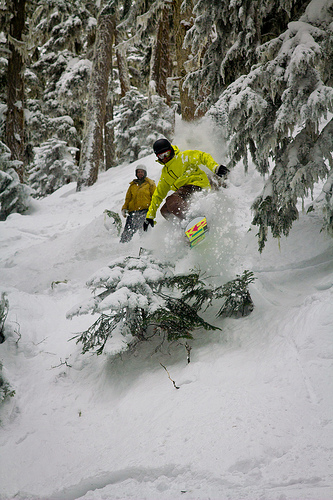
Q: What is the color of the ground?
A: White.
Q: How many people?
A: 2.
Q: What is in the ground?
A: Snow.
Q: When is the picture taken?
A: Daytime.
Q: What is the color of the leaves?
A: Green.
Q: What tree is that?
A: Pine.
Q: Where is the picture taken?
A: On a ski slope.